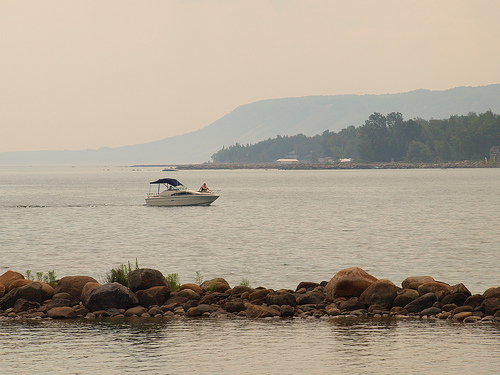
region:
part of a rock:
[392, 308, 409, 323]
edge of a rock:
[331, 305, 341, 321]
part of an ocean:
[328, 206, 339, 230]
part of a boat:
[177, 170, 204, 212]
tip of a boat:
[220, 195, 223, 199]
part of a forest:
[397, 143, 398, 146]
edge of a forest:
[399, 125, 401, 130]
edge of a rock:
[358, 293, 360, 295]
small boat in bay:
[129, 159, 237, 228]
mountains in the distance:
[202, 66, 483, 171]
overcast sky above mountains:
[30, 36, 180, 134]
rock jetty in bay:
[19, 248, 478, 355]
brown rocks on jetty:
[41, 259, 98, 298]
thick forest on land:
[236, 104, 498, 162]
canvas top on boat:
[152, 171, 187, 190]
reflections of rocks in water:
[132, 331, 435, 369]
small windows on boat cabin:
[173, 187, 194, 197]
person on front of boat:
[194, 180, 216, 194]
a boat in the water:
[104, 130, 301, 295]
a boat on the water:
[110, 160, 284, 272]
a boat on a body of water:
[93, 142, 356, 297]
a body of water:
[302, 176, 490, 285]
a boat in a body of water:
[74, 161, 335, 288]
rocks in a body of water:
[62, 236, 482, 372]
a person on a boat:
[111, 150, 266, 250]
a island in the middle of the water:
[205, 90, 495, 205]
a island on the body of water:
[201, 116, 488, 191]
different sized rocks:
[36, 244, 420, 371]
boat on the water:
[140, 168, 222, 233]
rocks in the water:
[278, 270, 480, 330]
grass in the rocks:
[96, 251, 153, 287]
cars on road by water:
[273, 150, 348, 167]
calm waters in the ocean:
[342, 179, 458, 261]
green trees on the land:
[370, 112, 491, 154]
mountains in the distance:
[239, 85, 337, 127]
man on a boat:
[193, 180, 212, 195]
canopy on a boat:
[152, 175, 187, 188]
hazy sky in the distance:
[30, 55, 158, 115]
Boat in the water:
[139, 143, 228, 240]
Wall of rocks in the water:
[94, 275, 489, 359]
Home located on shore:
[269, 143, 363, 175]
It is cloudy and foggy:
[52, 12, 260, 125]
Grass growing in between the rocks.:
[102, 249, 191, 307]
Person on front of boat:
[187, 178, 219, 204]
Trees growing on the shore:
[291, 82, 496, 164]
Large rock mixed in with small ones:
[325, 255, 380, 312]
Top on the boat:
[142, 160, 178, 200]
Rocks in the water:
[67, 153, 182, 171]